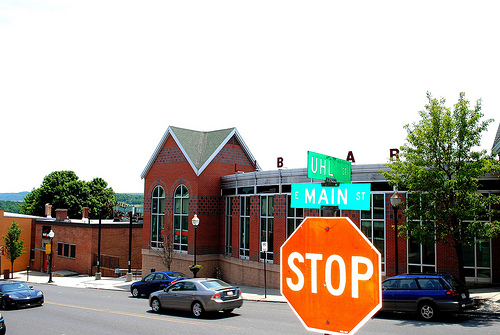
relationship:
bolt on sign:
[321, 224, 331, 232] [279, 216, 382, 335]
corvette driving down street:
[0, 278, 47, 311] [0, 279, 497, 334]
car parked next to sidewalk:
[373, 273, 475, 320] [5, 271, 498, 314]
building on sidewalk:
[31, 209, 139, 274] [37, 243, 207, 297]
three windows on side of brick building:
[57, 242, 77, 258] [33, 206, 143, 278]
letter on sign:
[348, 253, 373, 299] [275, 215, 386, 333]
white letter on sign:
[286, 251, 303, 292] [275, 215, 386, 333]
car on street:
[149, 278, 243, 316] [0, 274, 498, 333]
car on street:
[130, 270, 189, 298] [1, 279, 323, 334]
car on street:
[376, 276, 473, 328] [0, 279, 497, 334]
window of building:
[235, 192, 252, 258] [136, 118, 499, 301]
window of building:
[168, 180, 193, 255] [139, 121, 499, 324]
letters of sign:
[284, 247, 374, 303] [275, 215, 386, 333]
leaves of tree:
[366, 81, 498, 278] [377, 79, 483, 281]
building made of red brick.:
[136, 118, 499, 301] [150, 164, 183, 177]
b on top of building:
[273, 155, 284, 167] [136, 118, 499, 301]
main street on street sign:
[297, 183, 369, 212] [302, 148, 353, 182]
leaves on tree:
[378, 100, 498, 291] [378, 85, 484, 295]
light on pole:
[186, 212, 203, 228] [188, 222, 202, 275]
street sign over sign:
[285, 177, 380, 217] [279, 216, 382, 335]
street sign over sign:
[303, 147, 356, 184] [279, 216, 382, 335]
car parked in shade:
[381, 274, 467, 321] [398, 295, 499, 328]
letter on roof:
[231, 158, 244, 176] [216, 150, 423, 191]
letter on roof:
[251, 154, 261, 174] [216, 150, 423, 191]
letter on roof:
[272, 151, 290, 171] [216, 150, 423, 191]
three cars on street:
[9, 264, 240, 332] [0, 282, 485, 332]